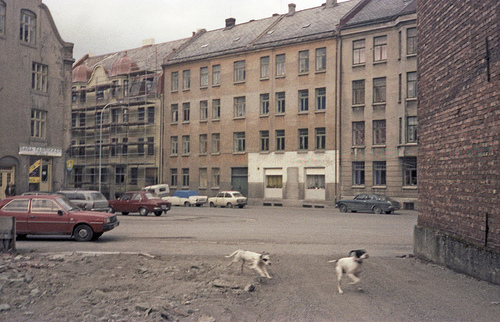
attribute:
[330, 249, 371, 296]
dog — white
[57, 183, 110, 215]
car — silver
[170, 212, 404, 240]
street — dusty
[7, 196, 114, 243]
car — red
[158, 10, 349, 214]
building — brown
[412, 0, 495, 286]
brick wall — red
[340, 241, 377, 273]
face — black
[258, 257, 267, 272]
eye — black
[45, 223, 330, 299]
street — dusty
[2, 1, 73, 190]
stone — curved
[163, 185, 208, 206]
car — white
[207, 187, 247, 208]
car — white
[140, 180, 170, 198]
car — white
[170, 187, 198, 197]
top — blue